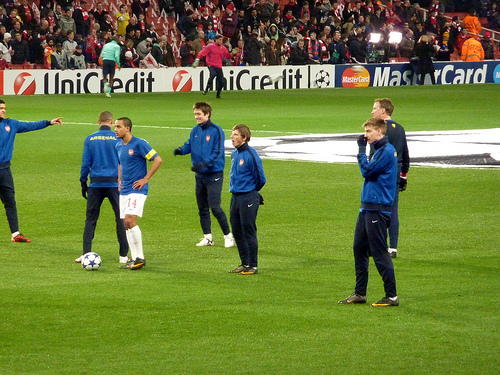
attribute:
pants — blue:
[340, 197, 411, 317]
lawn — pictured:
[102, 284, 327, 344]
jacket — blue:
[79, 127, 119, 187]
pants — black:
[78, 189, 131, 267]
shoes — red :
[335, 275, 445, 330]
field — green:
[0, 81, 500, 373]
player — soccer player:
[335, 117, 405, 312]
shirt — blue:
[113, 132, 160, 199]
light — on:
[391, 30, 406, 47]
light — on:
[365, 30, 382, 46]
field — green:
[11, 17, 484, 373]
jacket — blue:
[213, 143, 275, 202]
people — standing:
[253, 102, 385, 302]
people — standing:
[4, 7, 487, 96]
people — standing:
[0, 90, 467, 337]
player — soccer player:
[166, 90, 232, 248]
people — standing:
[80, 1, 420, 68]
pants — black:
[351, 211, 398, 296]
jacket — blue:
[353, 133, 405, 218]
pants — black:
[193, 167, 233, 242]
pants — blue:
[230, 190, 260, 270]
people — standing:
[80, 110, 116, 273]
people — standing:
[168, 100, 231, 255]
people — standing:
[109, 114, 160, 266]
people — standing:
[200, 30, 232, 102]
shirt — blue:
[346, 129, 400, 216]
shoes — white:
[0, 225, 409, 310]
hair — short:
[188, 96, 211, 118]